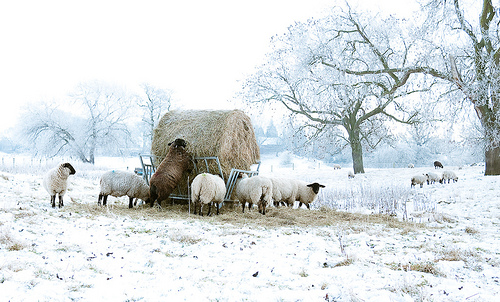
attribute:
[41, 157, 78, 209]
sheep — facing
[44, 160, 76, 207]
sheep — out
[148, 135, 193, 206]
sheep — out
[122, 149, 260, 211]
bars — metal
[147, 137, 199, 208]
sheep — brown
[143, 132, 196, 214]
sheep — brown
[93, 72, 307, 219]
building — distant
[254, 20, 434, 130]
branches — bare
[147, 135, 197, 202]
brown sheep — colored, different, one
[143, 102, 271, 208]
hay — bale 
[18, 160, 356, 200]
sheep — having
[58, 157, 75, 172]
face — black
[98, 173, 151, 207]
sheep — out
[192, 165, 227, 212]
sheep — out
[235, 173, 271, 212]
sheep — out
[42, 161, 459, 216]
sheep — female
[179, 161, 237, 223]
sheep — white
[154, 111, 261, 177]
straw — large , round 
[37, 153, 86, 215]
sheep — watching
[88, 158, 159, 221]
sheep — watching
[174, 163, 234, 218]
sheep — watching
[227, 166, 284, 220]
sheep — watching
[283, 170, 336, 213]
sheep — watching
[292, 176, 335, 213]
sheep — looking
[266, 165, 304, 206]
sheep — looking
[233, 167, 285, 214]
sheep — looking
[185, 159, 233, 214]
sheep — looking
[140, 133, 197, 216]
sheep — looking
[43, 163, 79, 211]
sheep — white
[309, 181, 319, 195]
face — black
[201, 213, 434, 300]
ground — frozen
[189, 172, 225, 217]
sheep — female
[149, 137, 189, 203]
sheep — male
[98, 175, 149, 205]
sheep — female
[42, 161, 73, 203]
sheep — female